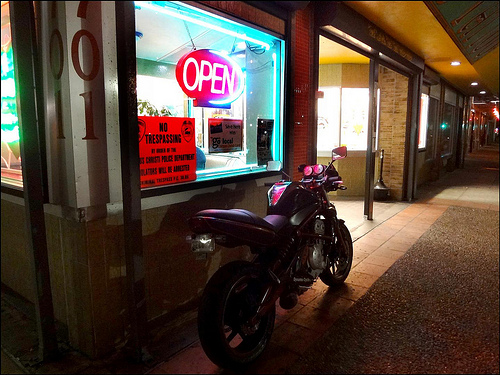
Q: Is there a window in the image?
A: Yes, there is a window.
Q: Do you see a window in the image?
A: Yes, there is a window.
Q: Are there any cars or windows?
A: Yes, there is a window.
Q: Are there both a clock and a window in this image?
A: No, there is a window but no clocks.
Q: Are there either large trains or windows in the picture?
A: Yes, there is a large window.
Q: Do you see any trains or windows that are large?
A: Yes, the window is large.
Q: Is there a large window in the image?
A: Yes, there is a large window.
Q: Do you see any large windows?
A: Yes, there is a large window.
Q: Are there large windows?
A: Yes, there is a large window.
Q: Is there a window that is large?
A: Yes, there is a window that is large.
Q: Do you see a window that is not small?
A: Yes, there is a large window.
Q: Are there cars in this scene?
A: No, there are no cars.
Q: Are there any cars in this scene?
A: No, there are no cars.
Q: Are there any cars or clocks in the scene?
A: No, there are no cars or clocks.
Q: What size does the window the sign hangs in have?
A: The window has large size.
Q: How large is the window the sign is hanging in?
A: The window is large.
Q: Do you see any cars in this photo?
A: No, there are no cars.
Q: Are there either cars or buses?
A: No, there are no cars or buses.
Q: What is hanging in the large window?
A: The sign is hanging in the window.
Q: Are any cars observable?
A: No, there are no cars.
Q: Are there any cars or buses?
A: No, there are no cars or buses.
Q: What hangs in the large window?
A: The sign hangs in the window.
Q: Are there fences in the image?
A: No, there are no fences.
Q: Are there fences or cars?
A: No, there are no fences or cars.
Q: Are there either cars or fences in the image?
A: No, there are no fences or cars.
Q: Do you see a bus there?
A: No, there are no buses.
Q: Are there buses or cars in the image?
A: No, there are no buses or cars.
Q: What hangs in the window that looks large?
A: The sign hangs in the window.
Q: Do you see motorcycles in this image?
A: Yes, there is a motorcycle.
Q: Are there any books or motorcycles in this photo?
A: Yes, there is a motorcycle.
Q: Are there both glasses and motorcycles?
A: No, there is a motorcycle but no glasses.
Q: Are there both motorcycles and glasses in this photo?
A: No, there is a motorcycle but no glasses.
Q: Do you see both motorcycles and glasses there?
A: No, there is a motorcycle but no glasses.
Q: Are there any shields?
A: No, there are no shields.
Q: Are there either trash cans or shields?
A: No, there are no shields or trash cans.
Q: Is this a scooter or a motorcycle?
A: This is a motorcycle.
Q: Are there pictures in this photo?
A: No, there are no pictures.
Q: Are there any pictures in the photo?
A: No, there are no pictures.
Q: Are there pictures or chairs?
A: No, there are no pictures or chairs.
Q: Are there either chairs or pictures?
A: No, there are no pictures or chairs.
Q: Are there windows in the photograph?
A: Yes, there is a window.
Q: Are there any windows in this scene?
A: Yes, there is a window.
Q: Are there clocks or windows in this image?
A: Yes, there is a window.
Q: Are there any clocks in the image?
A: No, there are no clocks.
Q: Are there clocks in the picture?
A: No, there are no clocks.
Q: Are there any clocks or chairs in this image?
A: No, there are no clocks or chairs.